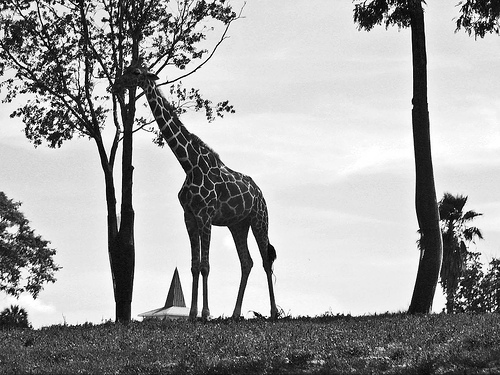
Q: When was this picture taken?
A: During the day.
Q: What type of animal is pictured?
A: A giraffe.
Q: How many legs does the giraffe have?
A: Four.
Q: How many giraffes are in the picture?
A: One.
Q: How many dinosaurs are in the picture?
A: Zero.